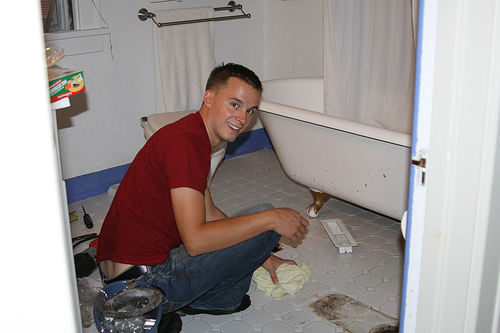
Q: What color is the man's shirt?
A: Red.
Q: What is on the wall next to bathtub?
A: Towel Rack.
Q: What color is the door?
A: White.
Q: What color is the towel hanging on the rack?
A: White.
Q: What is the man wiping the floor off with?
A: A towel.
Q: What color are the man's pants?
A: Blue.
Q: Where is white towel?
A: Hanging on wall.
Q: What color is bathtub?
A: White.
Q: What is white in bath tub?
A: Shower curtain.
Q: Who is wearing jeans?
A: A male.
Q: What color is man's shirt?
A: Red.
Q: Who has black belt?
A: A male.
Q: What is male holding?
A: A towel.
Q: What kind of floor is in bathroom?
A: White tile floor.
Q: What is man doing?
A: Working in bathroom.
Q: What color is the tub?
A: White.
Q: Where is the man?
A: Bathroom.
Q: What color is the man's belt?
A: Black.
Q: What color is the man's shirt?
A: Red.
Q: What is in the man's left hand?
A: Towel.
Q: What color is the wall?
A: White.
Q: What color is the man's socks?
A: Black.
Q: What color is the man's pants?
A: Blue.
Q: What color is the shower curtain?
A: White.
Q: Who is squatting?
A: Young man.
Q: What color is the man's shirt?
A: Red.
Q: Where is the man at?
A: The man is in a bathroom.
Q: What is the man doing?
A: The man is repairing the floor.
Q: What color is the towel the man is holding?
A: The towel is white.